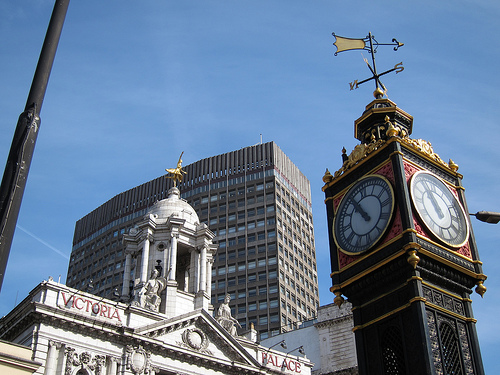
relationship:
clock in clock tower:
[332, 175, 397, 251] [323, 30, 480, 374]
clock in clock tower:
[410, 170, 471, 247] [323, 30, 480, 374]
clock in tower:
[410, 170, 468, 247] [322, 32, 487, 372]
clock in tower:
[410, 170, 471, 247] [298, 11, 493, 357]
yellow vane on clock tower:
[329, 21, 392, 63] [317, 23, 492, 370]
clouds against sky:
[38, 65, 221, 159] [135, 30, 303, 97]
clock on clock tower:
[332, 175, 397, 255] [317, 23, 492, 370]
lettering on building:
[60, 292, 124, 322] [4, 149, 318, 373]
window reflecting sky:
[227, 227, 237, 238] [1, 0, 496, 374]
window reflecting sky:
[242, 222, 258, 232] [1, 0, 496, 374]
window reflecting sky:
[255, 222, 269, 231] [1, 0, 496, 374]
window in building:
[227, 227, 237, 238] [61, 140, 310, 340]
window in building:
[242, 222, 258, 232] [61, 140, 310, 340]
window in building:
[255, 222, 269, 231] [61, 140, 310, 340]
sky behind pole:
[6, 14, 467, 184] [10, 1, 90, 184]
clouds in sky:
[137, 45, 214, 109] [1, 0, 496, 374]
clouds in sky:
[137, 45, 214, 109] [128, 106, 263, 123]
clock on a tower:
[332, 175, 397, 255] [355, 46, 487, 330]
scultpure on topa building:
[164, 149, 188, 186] [4, 149, 318, 373]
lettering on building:
[57, 289, 127, 326] [56, 302, 307, 372]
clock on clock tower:
[332, 175, 397, 255] [323, 30, 485, 375]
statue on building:
[216, 295, 241, 337] [0, 25, 497, 375]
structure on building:
[110, 147, 220, 318] [0, 25, 497, 375]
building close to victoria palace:
[64, 122, 366, 362] [87, 208, 259, 372]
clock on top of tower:
[410, 170, 471, 247] [338, 38, 486, 363]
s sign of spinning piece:
[392, 61, 404, 76] [331, 29, 405, 99]